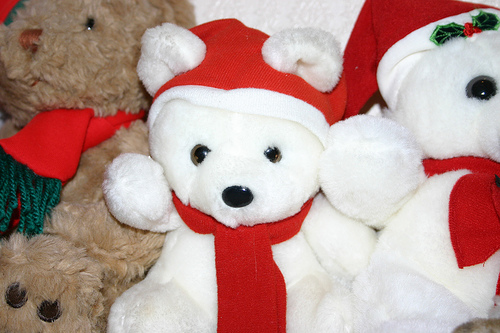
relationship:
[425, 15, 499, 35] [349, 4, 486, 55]
mistle toe attached to hat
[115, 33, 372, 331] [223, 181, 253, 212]
middle bear has nose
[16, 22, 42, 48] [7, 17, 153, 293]
nose on bear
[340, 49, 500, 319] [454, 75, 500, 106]
bear has eye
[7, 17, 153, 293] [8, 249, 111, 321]
bear has foot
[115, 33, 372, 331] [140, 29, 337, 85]
middle bear has ears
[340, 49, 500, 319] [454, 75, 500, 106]
stuffed animal has eye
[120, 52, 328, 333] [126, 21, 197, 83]
toy has ear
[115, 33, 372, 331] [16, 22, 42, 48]
middle bear has nose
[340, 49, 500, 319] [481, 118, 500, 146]
stuffed animal has nose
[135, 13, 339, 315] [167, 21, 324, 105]
teddy bar wearing hat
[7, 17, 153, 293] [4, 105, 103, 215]
bear wearing scarf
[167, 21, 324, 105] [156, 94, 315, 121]
hat has rim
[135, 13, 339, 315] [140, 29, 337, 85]
teddy bar has ears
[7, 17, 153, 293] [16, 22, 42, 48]
bear has nose